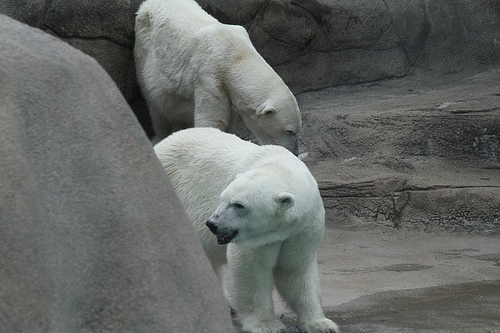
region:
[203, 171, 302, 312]
the bear is white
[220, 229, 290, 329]
the bear is white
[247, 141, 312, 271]
the bear is white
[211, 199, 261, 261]
the bear is white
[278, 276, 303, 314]
the bear is white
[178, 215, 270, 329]
the bear is white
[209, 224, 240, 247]
Polar bear mouth is open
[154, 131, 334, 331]
Polar bear is white and big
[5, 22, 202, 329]
Boulder is big and grey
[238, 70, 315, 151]
Polar bear head is lowered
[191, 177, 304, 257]
Polar bear head is turned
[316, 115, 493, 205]
Steps made of rock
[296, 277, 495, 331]
Polar bear foot in water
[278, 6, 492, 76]
Big rock between polar bear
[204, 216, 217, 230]
Polar bear has black nose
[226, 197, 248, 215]
Polar bear has dark eyes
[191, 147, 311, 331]
a polar bear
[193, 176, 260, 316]
a polar bear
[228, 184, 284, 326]
a polar bear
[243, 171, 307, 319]
a polar bear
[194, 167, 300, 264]
Bear head is turned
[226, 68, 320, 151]
Bear head is lowered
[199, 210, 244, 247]
Bear's mouth is open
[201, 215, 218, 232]
Bear's nose is black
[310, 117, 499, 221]
Rock steps near bear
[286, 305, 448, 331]
Bear's paw in water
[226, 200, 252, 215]
Bear has dark eye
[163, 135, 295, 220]
Bear's fur is white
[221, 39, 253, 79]
Brown spot on bear's fur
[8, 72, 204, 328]
Big rock next to bear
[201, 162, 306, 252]
the head of a polar bear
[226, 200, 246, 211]
the eye of a polar bear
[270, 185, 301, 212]
the ear of a polar bear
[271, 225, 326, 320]
the leg of a polar bear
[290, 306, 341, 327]
the paw of a polar bear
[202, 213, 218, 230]
the nose of a polar bear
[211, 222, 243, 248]
the mouth of a polar bear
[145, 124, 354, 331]
a large white polar bear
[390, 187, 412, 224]
a crack in the rock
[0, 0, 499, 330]
large gray rocks